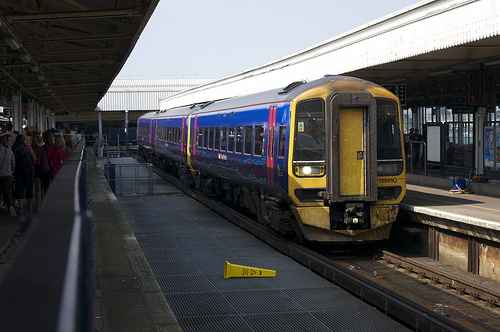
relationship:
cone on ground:
[219, 256, 283, 282] [93, 151, 310, 329]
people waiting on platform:
[0, 117, 78, 219] [21, 142, 148, 326]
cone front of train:
[219, 256, 283, 282] [123, 69, 417, 250]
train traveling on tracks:
[123, 69, 417, 250] [316, 249, 499, 328]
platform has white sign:
[21, 142, 148, 326] [57, 145, 92, 332]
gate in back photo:
[104, 122, 137, 152] [4, 3, 497, 330]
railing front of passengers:
[53, 124, 96, 331] [0, 117, 78, 219]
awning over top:
[320, 14, 499, 53] [197, 7, 494, 61]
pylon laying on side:
[219, 256, 283, 282] [93, 151, 310, 329]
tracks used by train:
[316, 249, 499, 328] [123, 69, 417, 250]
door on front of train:
[333, 101, 370, 197] [123, 69, 417, 250]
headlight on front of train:
[297, 158, 319, 175] [123, 69, 417, 250]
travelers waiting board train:
[0, 117, 78, 219] [123, 69, 417, 250]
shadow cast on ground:
[408, 187, 486, 218] [410, 181, 499, 240]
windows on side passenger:
[400, 74, 498, 172] [0, 117, 78, 219]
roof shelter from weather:
[6, 1, 160, 114] [4, 3, 497, 330]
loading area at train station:
[21, 142, 148, 326] [58, 140, 244, 328]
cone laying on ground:
[219, 256, 283, 282] [93, 151, 310, 329]